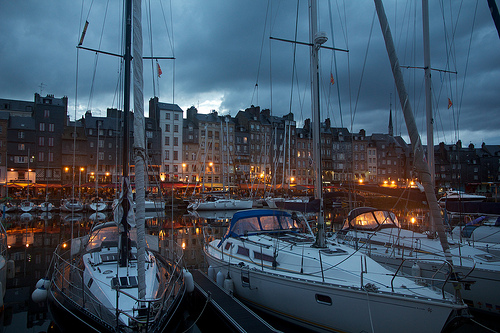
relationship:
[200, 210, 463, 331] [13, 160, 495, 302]
boat docked at marina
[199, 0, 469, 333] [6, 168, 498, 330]
boats docked in marina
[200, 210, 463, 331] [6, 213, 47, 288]
boat docked in water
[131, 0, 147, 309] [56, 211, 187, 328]
railing on front of boat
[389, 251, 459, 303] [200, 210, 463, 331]
silver railing on front of boat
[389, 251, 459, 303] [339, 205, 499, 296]
silver railing on front of boat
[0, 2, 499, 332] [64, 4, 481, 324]
boats have masts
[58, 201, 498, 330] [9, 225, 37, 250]
boats float in water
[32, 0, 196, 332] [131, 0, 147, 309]
boats has railing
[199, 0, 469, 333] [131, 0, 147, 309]
boats has railing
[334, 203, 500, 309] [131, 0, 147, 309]
boats has railing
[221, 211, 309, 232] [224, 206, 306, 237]
windows has cover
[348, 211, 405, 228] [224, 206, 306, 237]
windows has cover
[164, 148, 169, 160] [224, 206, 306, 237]
windows has cover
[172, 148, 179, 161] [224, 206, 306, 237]
windows has cover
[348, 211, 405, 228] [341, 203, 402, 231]
windows has cover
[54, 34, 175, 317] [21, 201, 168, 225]
boats have sterns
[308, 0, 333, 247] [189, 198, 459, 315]
masts on boat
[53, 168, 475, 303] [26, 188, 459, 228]
boats on water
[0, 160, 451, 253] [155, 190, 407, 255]
lights reflect on water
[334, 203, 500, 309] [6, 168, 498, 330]
boats docked at marina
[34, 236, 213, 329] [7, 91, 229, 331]
railing around boat